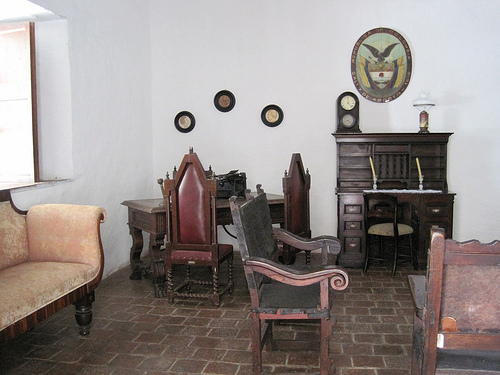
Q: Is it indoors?
A: Yes, it is indoors.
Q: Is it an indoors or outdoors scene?
A: It is indoors.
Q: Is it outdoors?
A: No, it is indoors.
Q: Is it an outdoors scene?
A: No, it is indoors.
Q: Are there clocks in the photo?
A: Yes, there is a clock.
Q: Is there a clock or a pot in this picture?
A: Yes, there is a clock.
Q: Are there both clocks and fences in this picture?
A: No, there is a clock but no fences.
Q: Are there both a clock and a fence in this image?
A: No, there is a clock but no fences.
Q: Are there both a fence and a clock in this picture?
A: No, there is a clock but no fences.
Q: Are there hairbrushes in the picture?
A: No, there are no hairbrushes.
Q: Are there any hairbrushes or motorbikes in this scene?
A: No, there are no hairbrushes or motorbikes.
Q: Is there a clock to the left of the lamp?
A: Yes, there is a clock to the left of the lamp.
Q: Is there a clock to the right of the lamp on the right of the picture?
A: No, the clock is to the left of the lamp.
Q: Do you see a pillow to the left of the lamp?
A: No, there is a clock to the left of the lamp.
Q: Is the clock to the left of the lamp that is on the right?
A: Yes, the clock is to the left of the lamp.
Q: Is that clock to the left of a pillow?
A: No, the clock is to the left of the lamp.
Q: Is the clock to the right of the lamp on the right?
A: No, the clock is to the left of the lamp.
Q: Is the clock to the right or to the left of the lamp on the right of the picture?
A: The clock is to the left of the lamp.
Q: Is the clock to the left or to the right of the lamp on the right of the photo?
A: The clock is to the left of the lamp.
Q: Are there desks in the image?
A: Yes, there is a desk.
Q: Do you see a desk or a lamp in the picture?
A: Yes, there is a desk.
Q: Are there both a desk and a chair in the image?
A: Yes, there are both a desk and a chair.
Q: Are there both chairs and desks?
A: Yes, there are both a desk and a chair.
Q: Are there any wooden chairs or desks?
A: Yes, there is a wood desk.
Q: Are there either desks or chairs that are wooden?
A: Yes, the desk is wooden.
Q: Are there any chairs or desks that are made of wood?
A: Yes, the desk is made of wood.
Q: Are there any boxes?
A: No, there are no boxes.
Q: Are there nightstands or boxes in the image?
A: No, there are no boxes or nightstands.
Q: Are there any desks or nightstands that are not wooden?
A: No, there is a desk but it is wooden.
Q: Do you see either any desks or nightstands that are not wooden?
A: No, there is a desk but it is wooden.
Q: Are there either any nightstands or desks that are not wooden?
A: No, there is a desk but it is wooden.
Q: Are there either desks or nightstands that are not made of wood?
A: No, there is a desk but it is made of wood.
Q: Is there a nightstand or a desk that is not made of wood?
A: No, there is a desk but it is made of wood.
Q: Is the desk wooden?
A: Yes, the desk is wooden.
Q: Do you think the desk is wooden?
A: Yes, the desk is wooden.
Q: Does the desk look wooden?
A: Yes, the desk is wooden.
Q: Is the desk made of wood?
A: Yes, the desk is made of wood.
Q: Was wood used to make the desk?
A: Yes, the desk is made of wood.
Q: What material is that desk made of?
A: The desk is made of wood.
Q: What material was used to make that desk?
A: The desk is made of wood.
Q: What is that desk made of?
A: The desk is made of wood.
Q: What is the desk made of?
A: The desk is made of wood.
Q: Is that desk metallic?
A: No, the desk is wooden.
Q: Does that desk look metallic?
A: No, the desk is wooden.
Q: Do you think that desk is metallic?
A: No, the desk is wooden.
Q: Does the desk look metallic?
A: No, the desk is wooden.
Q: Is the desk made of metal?
A: No, the desk is made of wood.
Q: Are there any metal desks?
A: No, there is a desk but it is made of wood.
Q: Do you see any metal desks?
A: No, there is a desk but it is made of wood.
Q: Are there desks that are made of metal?
A: No, there is a desk but it is made of wood.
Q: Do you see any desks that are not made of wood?
A: No, there is a desk but it is made of wood.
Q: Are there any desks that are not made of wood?
A: No, there is a desk but it is made of wood.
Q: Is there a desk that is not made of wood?
A: No, there is a desk but it is made of wood.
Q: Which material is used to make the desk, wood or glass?
A: The desk is made of wood.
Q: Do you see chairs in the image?
A: Yes, there is a chair.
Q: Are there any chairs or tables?
A: Yes, there is a chair.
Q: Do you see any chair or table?
A: Yes, there is a chair.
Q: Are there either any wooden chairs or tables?
A: Yes, there is a wood chair.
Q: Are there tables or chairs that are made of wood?
A: Yes, the chair is made of wood.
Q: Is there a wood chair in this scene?
A: Yes, there is a wood chair.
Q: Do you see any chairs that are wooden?
A: Yes, there is a chair that is wooden.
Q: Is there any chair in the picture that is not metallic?
A: Yes, there is a wooden chair.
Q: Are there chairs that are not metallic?
A: Yes, there is a wooden chair.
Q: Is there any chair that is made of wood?
A: Yes, there is a chair that is made of wood.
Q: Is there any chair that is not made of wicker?
A: Yes, there is a chair that is made of wood.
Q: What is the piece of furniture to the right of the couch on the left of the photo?
A: The piece of furniture is a chair.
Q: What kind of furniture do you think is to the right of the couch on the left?
A: The piece of furniture is a chair.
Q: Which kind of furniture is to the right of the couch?
A: The piece of furniture is a chair.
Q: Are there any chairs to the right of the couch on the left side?
A: Yes, there is a chair to the right of the couch.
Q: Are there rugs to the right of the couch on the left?
A: No, there is a chair to the right of the couch.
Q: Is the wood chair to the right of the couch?
A: Yes, the chair is to the right of the couch.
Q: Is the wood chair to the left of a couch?
A: No, the chair is to the right of a couch.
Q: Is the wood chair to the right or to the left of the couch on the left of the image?
A: The chair is to the right of the couch.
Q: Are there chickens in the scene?
A: No, there are no chickens.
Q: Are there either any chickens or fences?
A: No, there are no chickens or fences.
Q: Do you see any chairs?
A: Yes, there is a chair.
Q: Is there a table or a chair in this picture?
A: Yes, there is a chair.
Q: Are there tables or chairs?
A: Yes, there is a chair.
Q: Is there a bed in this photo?
A: No, there are no beds.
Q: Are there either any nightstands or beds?
A: No, there are no beds or nightstands.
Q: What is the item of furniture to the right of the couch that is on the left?
A: The piece of furniture is a chair.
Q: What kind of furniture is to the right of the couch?
A: The piece of furniture is a chair.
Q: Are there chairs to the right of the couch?
A: Yes, there is a chair to the right of the couch.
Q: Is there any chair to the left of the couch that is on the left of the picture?
A: No, the chair is to the right of the couch.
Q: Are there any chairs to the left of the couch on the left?
A: No, the chair is to the right of the couch.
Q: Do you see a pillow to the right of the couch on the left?
A: No, there is a chair to the right of the couch.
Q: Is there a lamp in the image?
A: Yes, there is a lamp.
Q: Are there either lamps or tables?
A: Yes, there is a lamp.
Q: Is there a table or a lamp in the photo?
A: Yes, there is a lamp.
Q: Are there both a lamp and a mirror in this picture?
A: No, there is a lamp but no mirrors.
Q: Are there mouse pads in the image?
A: No, there are no mouse pads.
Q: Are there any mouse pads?
A: No, there are no mouse pads.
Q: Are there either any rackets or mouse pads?
A: No, there are no mouse pads or rackets.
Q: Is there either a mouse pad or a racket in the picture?
A: No, there are no mouse pads or rackets.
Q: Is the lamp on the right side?
A: Yes, the lamp is on the right of the image.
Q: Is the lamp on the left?
A: No, the lamp is on the right of the image.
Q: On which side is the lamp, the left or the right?
A: The lamp is on the right of the image.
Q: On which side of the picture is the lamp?
A: The lamp is on the right of the image.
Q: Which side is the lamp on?
A: The lamp is on the right of the image.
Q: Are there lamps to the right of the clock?
A: Yes, there is a lamp to the right of the clock.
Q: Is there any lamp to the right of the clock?
A: Yes, there is a lamp to the right of the clock.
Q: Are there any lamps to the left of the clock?
A: No, the lamp is to the right of the clock.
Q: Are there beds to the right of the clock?
A: No, there is a lamp to the right of the clock.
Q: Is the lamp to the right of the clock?
A: Yes, the lamp is to the right of the clock.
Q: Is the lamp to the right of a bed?
A: No, the lamp is to the right of the clock.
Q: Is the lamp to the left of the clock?
A: No, the lamp is to the right of the clock.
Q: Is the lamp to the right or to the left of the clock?
A: The lamp is to the right of the clock.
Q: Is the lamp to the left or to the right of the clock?
A: The lamp is to the right of the clock.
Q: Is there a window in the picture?
A: Yes, there is a window.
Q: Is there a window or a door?
A: Yes, there is a window.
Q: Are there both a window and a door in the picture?
A: No, there is a window but no doors.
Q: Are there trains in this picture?
A: No, there are no trains.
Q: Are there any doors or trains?
A: No, there are no trains or doors.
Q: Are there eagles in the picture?
A: Yes, there is an eagle.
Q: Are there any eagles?
A: Yes, there is an eagle.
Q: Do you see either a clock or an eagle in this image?
A: Yes, there is an eagle.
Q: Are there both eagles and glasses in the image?
A: No, there is an eagle but no glasses.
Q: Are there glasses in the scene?
A: No, there are no glasses.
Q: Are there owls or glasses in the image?
A: No, there are no glasses or owls.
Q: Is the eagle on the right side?
A: Yes, the eagle is on the right of the image.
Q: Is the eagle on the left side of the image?
A: No, the eagle is on the right of the image.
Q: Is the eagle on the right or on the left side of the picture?
A: The eagle is on the right of the image.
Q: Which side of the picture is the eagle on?
A: The eagle is on the right of the image.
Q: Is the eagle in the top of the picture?
A: Yes, the eagle is in the top of the image.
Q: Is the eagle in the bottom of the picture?
A: No, the eagle is in the top of the image.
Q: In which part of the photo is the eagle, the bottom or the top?
A: The eagle is in the top of the image.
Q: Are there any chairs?
A: Yes, there is a chair.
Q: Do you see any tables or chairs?
A: Yes, there is a chair.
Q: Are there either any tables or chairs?
A: Yes, there is a chair.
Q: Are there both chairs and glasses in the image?
A: No, there is a chair but no glasses.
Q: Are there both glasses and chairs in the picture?
A: No, there is a chair but no glasses.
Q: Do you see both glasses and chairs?
A: No, there is a chair but no glasses.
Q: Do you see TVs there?
A: No, there are no tvs.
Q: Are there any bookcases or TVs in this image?
A: No, there are no TVs or bookcases.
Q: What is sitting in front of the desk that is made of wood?
A: The chair is sitting in front of the desk.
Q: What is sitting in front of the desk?
A: The chair is sitting in front of the desk.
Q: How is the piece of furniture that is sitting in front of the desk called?
A: The piece of furniture is a chair.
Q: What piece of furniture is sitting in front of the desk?
A: The piece of furniture is a chair.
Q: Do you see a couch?
A: Yes, there is a couch.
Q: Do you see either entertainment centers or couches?
A: Yes, there is a couch.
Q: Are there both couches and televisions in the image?
A: No, there is a couch but no televisions.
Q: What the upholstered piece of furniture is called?
A: The piece of furniture is a couch.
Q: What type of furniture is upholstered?
A: The furniture is a couch.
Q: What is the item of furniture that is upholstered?
A: The piece of furniture is a couch.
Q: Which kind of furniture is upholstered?
A: The furniture is a couch.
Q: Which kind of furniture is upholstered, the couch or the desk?
A: The couch is upholstered.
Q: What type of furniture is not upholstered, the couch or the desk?
A: The desk is not upholstered.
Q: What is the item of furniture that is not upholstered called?
A: The piece of furniture is a desk.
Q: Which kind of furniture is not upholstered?
A: The furniture is a desk.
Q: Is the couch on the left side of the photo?
A: Yes, the couch is on the left of the image.